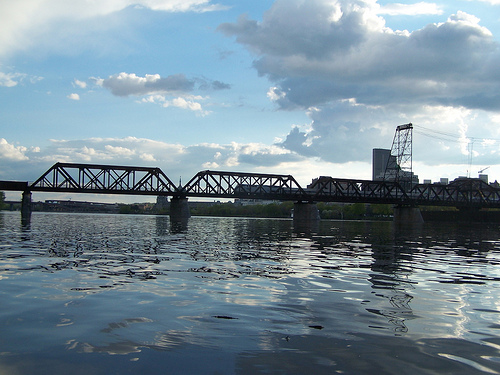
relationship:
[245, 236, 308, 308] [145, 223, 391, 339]
ripple on water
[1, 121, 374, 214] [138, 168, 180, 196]
bridge has braces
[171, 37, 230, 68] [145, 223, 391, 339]
sky in water